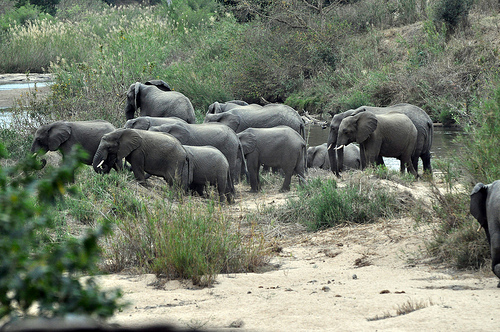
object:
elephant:
[335, 112, 420, 176]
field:
[2, 114, 500, 330]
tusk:
[334, 143, 343, 150]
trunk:
[337, 139, 346, 176]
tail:
[423, 120, 437, 167]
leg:
[407, 153, 418, 179]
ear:
[355, 111, 378, 144]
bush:
[1, 134, 124, 331]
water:
[2, 107, 485, 174]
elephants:
[93, 128, 191, 198]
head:
[338, 115, 373, 145]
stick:
[270, 219, 299, 242]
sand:
[168, 257, 451, 329]